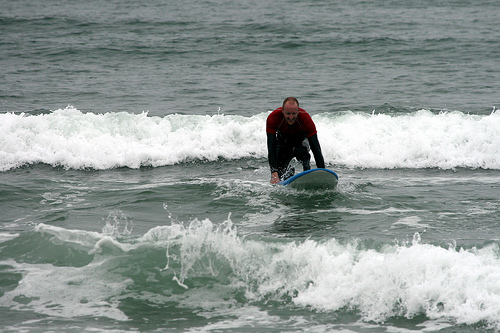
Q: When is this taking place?
A: Daytime.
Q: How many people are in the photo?
A: One.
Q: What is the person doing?
A: Surfing.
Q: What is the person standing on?
A: Surfboard.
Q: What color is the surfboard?
A: Blue and white.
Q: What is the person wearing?
A: Wetsuit.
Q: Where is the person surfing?
A: Ocean.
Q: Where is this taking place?
A: In the ocean.